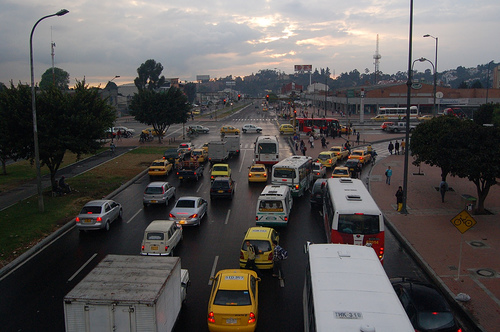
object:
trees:
[409, 102, 500, 212]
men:
[245, 240, 288, 280]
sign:
[449, 209, 479, 235]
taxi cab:
[207, 268, 261, 332]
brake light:
[204, 308, 217, 327]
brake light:
[247, 308, 255, 326]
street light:
[29, 9, 69, 214]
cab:
[188, 207, 300, 324]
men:
[245, 240, 264, 276]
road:
[0, 100, 467, 332]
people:
[53, 180, 67, 196]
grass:
[76, 173, 103, 195]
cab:
[200, 261, 270, 330]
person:
[59, 175, 72, 193]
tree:
[0, 75, 114, 191]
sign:
[294, 65, 312, 72]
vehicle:
[255, 184, 293, 228]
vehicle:
[168, 196, 209, 227]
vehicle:
[75, 200, 122, 233]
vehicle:
[248, 164, 267, 184]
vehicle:
[210, 164, 232, 180]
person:
[272, 240, 288, 279]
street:
[1, 97, 483, 330]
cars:
[92, 160, 444, 322]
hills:
[181, 63, 499, 99]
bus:
[320, 176, 387, 262]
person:
[385, 166, 392, 185]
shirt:
[385, 169, 392, 176]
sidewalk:
[365, 144, 500, 332]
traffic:
[64, 118, 409, 329]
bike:
[450, 213, 477, 235]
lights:
[208, 312, 256, 323]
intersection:
[129, 109, 394, 159]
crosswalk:
[170, 141, 297, 159]